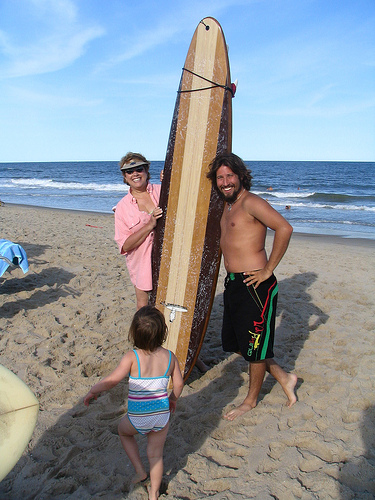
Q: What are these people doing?
A: Having fun at the beach.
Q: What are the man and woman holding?
A: A surfboard.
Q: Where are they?
A: At the beach.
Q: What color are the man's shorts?
A: Black.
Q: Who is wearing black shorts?
A: The man.